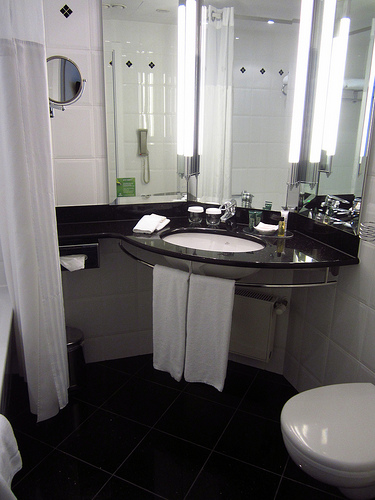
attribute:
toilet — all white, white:
[279, 384, 374, 500]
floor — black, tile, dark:
[1, 353, 374, 499]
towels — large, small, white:
[151, 263, 237, 395]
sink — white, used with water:
[160, 224, 269, 282]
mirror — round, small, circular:
[46, 56, 88, 114]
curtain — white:
[1, 0, 70, 422]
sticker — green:
[116, 178, 135, 198]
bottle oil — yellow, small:
[277, 216, 286, 238]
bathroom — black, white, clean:
[1, 1, 372, 500]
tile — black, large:
[155, 391, 233, 448]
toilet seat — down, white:
[281, 383, 374, 473]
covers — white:
[188, 206, 222, 215]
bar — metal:
[116, 241, 340, 289]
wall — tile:
[44, 0, 112, 209]